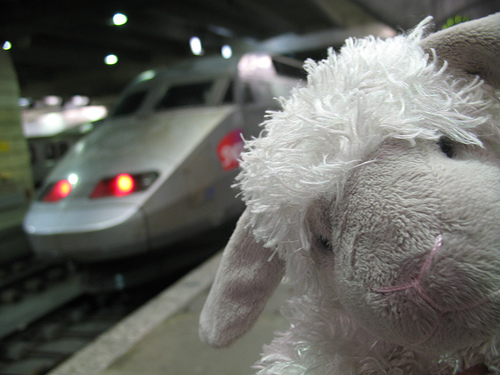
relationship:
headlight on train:
[110, 171, 137, 195] [17, 24, 385, 302]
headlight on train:
[43, 177, 72, 201] [17, 24, 385, 302]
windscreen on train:
[154, 79, 218, 109] [23, 51, 313, 299]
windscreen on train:
[104, 87, 148, 115] [23, 51, 313, 299]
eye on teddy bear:
[317, 226, 337, 258] [193, 9, 497, 366]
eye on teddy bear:
[439, 131, 460, 161] [193, 9, 497, 366]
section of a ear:
[230, 267, 252, 297] [192, 190, 292, 347]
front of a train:
[25, 203, 149, 263] [20, 46, 300, 261]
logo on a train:
[217, 130, 245, 171] [20, 46, 300, 261]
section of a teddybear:
[320, 314, 352, 353] [199, 20, 485, 359]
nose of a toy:
[401, 263, 425, 300] [202, 11, 499, 375]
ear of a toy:
[198, 210, 289, 348] [202, 11, 499, 375]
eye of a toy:
[440, 138, 454, 157] [202, 11, 499, 375]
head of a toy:
[196, 30, 481, 355] [202, 11, 499, 375]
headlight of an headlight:
[116, 173, 134, 193] [116, 173, 134, 193]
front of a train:
[23, 210, 141, 252] [20, 46, 300, 261]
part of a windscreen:
[180, 88, 195, 101] [156, 81, 211, 109]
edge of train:
[139, 111, 226, 207] [19, 50, 273, 257]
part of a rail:
[40, 334, 66, 354] [10, 273, 123, 369]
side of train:
[226, 68, 276, 134] [20, 46, 300, 261]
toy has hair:
[191, 22, 476, 359] [230, 21, 479, 357]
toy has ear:
[191, 22, 476, 359] [198, 210, 289, 348]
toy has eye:
[202, 11, 499, 375] [320, 236, 332, 249]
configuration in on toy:
[366, 233, 461, 313] [191, 22, 476, 359]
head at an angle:
[196, 30, 481, 355] [200, 27, 484, 355]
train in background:
[22, 52, 318, 260] [12, 23, 264, 240]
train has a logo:
[19, 50, 273, 257] [216, 129, 252, 169]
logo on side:
[216, 129, 252, 169] [119, 91, 277, 259]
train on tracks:
[22, 52, 318, 260] [6, 255, 167, 367]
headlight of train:
[57, 180, 72, 197] [9, 36, 245, 285]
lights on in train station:
[94, 10, 133, 80] [2, 0, 473, 372]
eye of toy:
[440, 138, 454, 157] [202, 11, 499, 375]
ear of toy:
[181, 207, 293, 355] [202, 11, 499, 375]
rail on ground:
[0, 261, 198, 374] [9, 248, 179, 372]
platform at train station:
[46, 306, 266, 369] [2, 0, 473, 372]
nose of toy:
[375, 235, 440, 291] [202, 11, 499, 375]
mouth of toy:
[401, 289, 483, 367] [202, 11, 499, 375]